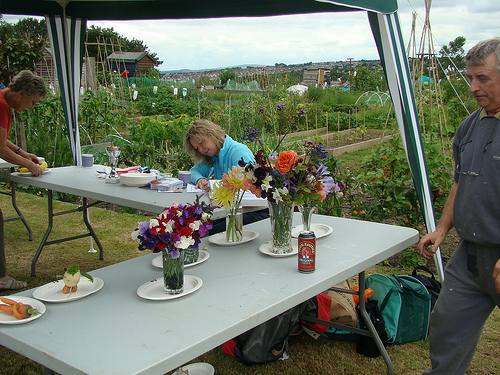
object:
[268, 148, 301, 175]
flowers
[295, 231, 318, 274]
can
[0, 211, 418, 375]
table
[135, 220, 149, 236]
flowers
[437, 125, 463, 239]
arm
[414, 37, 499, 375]
man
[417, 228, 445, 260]
hand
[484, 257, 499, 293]
hand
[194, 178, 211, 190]
hand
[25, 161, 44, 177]
hand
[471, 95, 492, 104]
mouth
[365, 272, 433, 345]
bag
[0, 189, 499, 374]
grass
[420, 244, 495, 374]
leg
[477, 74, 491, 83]
eye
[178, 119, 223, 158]
head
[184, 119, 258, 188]
lady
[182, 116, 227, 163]
curly hair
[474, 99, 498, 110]
chin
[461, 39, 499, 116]
man's face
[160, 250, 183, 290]
vase